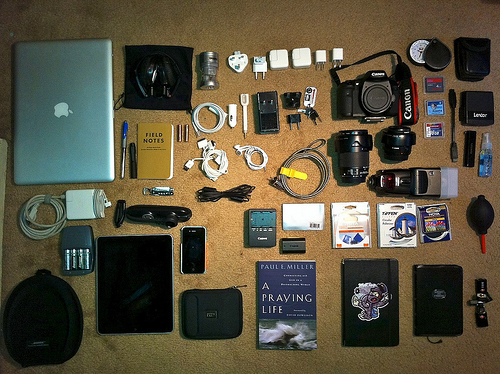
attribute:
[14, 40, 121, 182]
computer — laptop, Apple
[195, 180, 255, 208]
cord — pictured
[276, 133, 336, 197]
cord — pictured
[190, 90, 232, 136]
cord — pictured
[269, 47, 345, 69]
blocks — charging blocks, white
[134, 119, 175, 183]
notebook — blue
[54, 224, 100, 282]
charger — battery charger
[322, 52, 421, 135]
camera — cannon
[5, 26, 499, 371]
electronics — bundled together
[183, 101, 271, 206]
cords — bundled together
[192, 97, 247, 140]
wire — white 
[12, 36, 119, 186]
laptop — Grey 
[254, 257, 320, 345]
book — hardback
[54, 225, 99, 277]
container — Grey 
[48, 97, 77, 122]
logo — apple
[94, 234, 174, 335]
tablet — black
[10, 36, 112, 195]
laptop — computer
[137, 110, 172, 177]
notepad — Tan 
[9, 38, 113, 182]
apple laptop — grey 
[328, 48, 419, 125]
strap — black 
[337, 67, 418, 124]
camera — canon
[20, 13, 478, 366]
surface — brown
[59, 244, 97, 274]
batteries — four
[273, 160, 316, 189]
strap — yellow